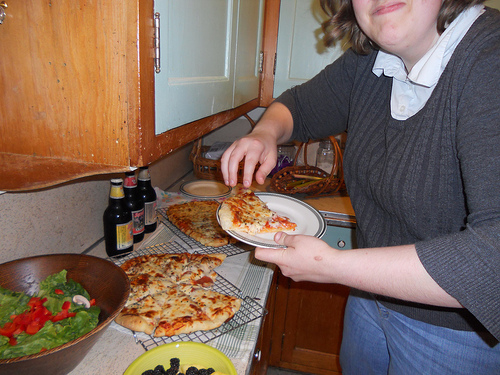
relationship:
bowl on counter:
[121, 342, 240, 372] [66, 168, 358, 373]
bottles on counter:
[103, 165, 157, 258] [56, 174, 264, 374]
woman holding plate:
[221, 0, 497, 370] [216, 187, 326, 247]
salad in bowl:
[0, 266, 102, 362] [44, 327, 105, 373]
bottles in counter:
[100, 160, 159, 258] [66, 168, 358, 373]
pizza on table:
[112, 247, 243, 330] [17, 188, 280, 373]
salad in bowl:
[0, 268, 100, 359] [2, 247, 136, 374]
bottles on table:
[103, 165, 157, 258] [59, 241, 281, 337]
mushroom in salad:
[53, 287, 110, 337] [0, 266, 102, 362]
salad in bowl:
[0, 268, 100, 359] [0, 242, 141, 371]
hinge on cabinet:
[147, 10, 164, 77] [0, 0, 349, 196]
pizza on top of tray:
[112, 253, 243, 338] [82, 230, 274, 373]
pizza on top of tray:
[112, 253, 243, 338] [97, 232, 274, 359]